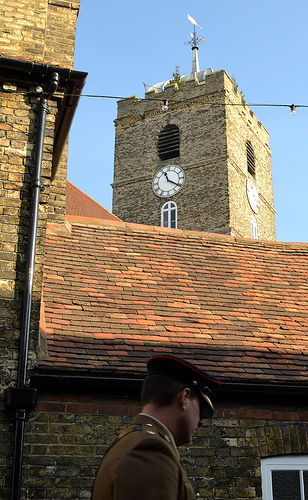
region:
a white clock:
[149, 164, 187, 197]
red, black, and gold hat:
[144, 354, 223, 422]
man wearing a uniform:
[88, 353, 223, 499]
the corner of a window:
[257, 452, 304, 496]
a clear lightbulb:
[287, 108, 295, 114]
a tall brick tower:
[113, 68, 272, 245]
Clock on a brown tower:
[151, 167, 187, 195]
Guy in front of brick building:
[86, 350, 224, 498]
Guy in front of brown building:
[95, 352, 223, 498]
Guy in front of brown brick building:
[97, 359, 228, 498]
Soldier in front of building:
[96, 350, 234, 499]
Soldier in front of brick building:
[95, 350, 220, 499]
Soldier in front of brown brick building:
[86, 354, 221, 499]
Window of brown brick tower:
[154, 121, 183, 157]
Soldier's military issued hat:
[146, 348, 220, 391]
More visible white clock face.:
[152, 164, 185, 198]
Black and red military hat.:
[147, 351, 223, 419]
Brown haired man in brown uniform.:
[91, 352, 222, 498]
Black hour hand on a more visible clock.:
[163, 172, 169, 181]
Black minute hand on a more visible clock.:
[166, 178, 181, 187]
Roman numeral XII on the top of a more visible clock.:
[165, 164, 169, 170]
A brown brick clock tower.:
[112, 69, 276, 239]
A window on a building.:
[160, 200, 178, 225]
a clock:
[151, 164, 186, 198]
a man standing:
[111, 356, 208, 499]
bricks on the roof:
[120, 225, 209, 290]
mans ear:
[176, 386, 194, 412]